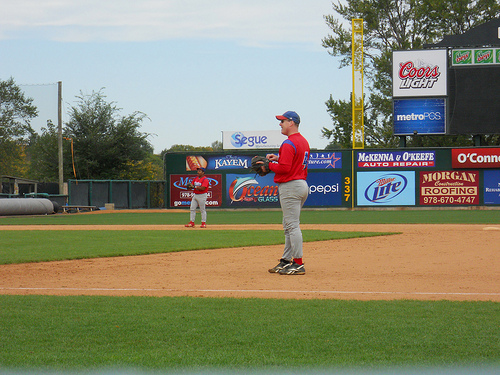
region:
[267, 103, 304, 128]
red and blue cap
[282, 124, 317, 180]
red and blue shirt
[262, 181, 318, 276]
fielder has grey pants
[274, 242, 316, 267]
fielder has red socks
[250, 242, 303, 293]
black and white shoes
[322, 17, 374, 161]
yellow fair pole on fence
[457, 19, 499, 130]
black scoreboard over fence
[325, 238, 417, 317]
white line on dirt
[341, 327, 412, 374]
green grass on field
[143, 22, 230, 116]
blue and white sky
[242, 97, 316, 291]
this is a baseball player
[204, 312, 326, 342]
this is the grass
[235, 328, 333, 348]
the grass is green in colour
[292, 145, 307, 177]
this is the back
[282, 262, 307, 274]
this is the shoe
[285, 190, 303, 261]
this is the leg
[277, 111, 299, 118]
this is the cap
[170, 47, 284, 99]
this is the sky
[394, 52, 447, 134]
these are the billboards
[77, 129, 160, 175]
these are the trees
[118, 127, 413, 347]
two people are in th field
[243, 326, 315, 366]
floor is coverd of grasses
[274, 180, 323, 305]
pants are gray in color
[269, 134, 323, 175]
the t shirt is red in color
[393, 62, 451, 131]
posters are red in color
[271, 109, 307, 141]
cape is blue in color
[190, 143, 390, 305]
peopple are playing bsebll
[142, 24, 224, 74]
sky is coverd of clouds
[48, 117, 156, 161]
plants are next to the playfield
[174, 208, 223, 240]
shoes are red in color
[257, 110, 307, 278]
man on the field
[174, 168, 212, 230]
man on the field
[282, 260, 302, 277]
shoe on the foot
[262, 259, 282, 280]
shoe on the foot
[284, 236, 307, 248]
the pants are tan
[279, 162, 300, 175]
the shirt is red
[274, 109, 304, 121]
hat on the head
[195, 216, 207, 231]
shoe on the foot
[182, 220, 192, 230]
shoe on the foot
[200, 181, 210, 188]
the shirt is red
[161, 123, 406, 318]
two people are standing in the fid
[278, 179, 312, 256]
pants are gray in color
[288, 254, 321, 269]
socks are red in coilor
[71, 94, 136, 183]
trees are beside the field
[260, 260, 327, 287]
shoes are black in color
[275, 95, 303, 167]
cape is blue red in color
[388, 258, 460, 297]
floor is coverd of soil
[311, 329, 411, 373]
floor is coverd of grasses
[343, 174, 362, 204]
words are witten in yellow paint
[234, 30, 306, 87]
sky is coverd of clouds